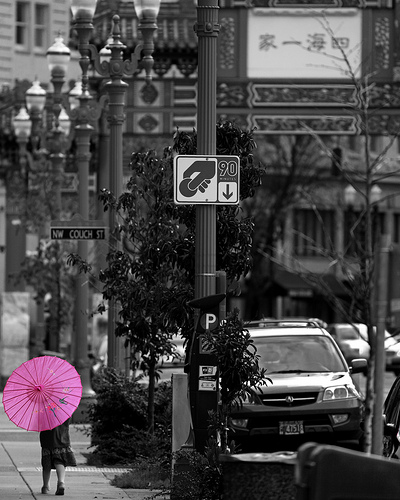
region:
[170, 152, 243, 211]
sign asking for 90 cents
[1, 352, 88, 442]
bright purple umbrella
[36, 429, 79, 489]
little girl's dress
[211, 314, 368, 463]
SUV parked on the road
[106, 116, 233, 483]
tree behind a pole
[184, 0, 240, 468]
lamp post with parking meter attached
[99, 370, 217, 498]
branches of tree laying on sidewalk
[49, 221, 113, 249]
sign says NW COUCH ST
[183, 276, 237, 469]
parking meter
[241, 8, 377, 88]
banner on the side of a building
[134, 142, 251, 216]
sign on the pole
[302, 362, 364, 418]
light on front of car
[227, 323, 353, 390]
front window of car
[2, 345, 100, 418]
purple umbrella in photo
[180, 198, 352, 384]
black and white photo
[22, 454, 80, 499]
legs of the person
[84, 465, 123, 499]
sidewalk under the lady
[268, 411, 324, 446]
license plate on front of car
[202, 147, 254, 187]
number on a sign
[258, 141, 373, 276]
blurry background of photo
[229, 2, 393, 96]
asian writing on sign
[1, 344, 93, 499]
woman carrying pink parasol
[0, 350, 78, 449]
pink parasol with floral design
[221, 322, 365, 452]
black acura vehicle parked on street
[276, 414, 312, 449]
license plate on front of vehicle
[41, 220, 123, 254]
street sign reading "NW Couch St"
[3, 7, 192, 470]
several light poles along street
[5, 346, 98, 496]
woman wearing dress carrying parisol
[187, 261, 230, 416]
several signs on lightpole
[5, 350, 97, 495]
woman walking down sidewalk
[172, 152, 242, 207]
this sign indicates where to pay for parking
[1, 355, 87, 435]
the umbrella is emphasized with color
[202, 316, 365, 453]
Acura made this car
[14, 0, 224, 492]
several street lights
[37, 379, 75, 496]
this woman is walking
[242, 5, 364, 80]
a sign in Japanese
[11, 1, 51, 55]
a double window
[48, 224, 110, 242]
a street sign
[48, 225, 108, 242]
this sign is in English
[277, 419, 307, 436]
this license plate has non-english characters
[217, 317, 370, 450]
A car parked downtown.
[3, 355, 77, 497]
Person carrying an umbrella.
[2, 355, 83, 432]
A bright pink umbrella.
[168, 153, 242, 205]
A sign on a pole.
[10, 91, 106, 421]
A street light on a sidewalk.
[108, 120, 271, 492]
Tree planted on a sidewalk.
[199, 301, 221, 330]
The letter P.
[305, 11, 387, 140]
A tree branch with no leaves.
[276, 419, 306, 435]
License plate on a car.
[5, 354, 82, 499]
A woman in a dress.